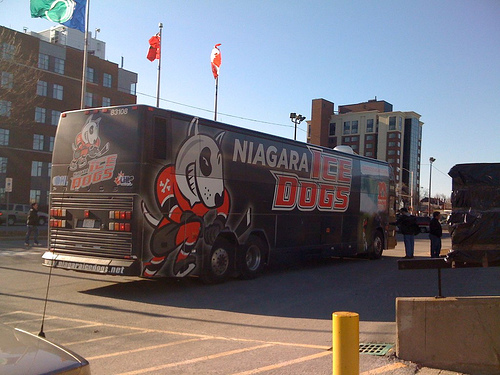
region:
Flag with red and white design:
[205, 38, 227, 78]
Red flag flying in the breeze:
[143, 29, 163, 65]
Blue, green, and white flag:
[26, 0, 91, 34]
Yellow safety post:
[323, 310, 364, 374]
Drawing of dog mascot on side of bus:
[142, 113, 227, 282]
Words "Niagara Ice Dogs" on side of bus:
[232, 140, 354, 212]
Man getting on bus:
[387, 200, 422, 260]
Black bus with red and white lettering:
[226, 130, 349, 218]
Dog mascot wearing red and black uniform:
[137, 118, 244, 282]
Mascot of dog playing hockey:
[133, 129, 237, 284]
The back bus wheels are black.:
[204, 233, 269, 279]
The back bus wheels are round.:
[207, 233, 268, 283]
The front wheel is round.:
[370, 228, 385, 256]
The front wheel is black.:
[370, 225, 382, 253]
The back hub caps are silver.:
[213, 251, 266, 273]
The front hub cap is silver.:
[373, 234, 385, 256]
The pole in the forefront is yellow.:
[325, 305, 365, 370]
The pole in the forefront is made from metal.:
[326, 313, 367, 372]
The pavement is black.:
[253, 285, 324, 319]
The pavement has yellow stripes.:
[110, 320, 290, 373]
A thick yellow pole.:
[330, 307, 362, 374]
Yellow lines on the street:
[4, 307, 412, 374]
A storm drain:
[335, 333, 395, 358]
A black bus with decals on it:
[42, 103, 399, 279]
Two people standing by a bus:
[387, 198, 447, 259]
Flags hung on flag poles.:
[27, 0, 233, 120]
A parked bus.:
[44, 98, 401, 286]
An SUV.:
[3, 198, 50, 229]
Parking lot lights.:
[290, 103, 437, 232]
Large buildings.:
[0, 15, 422, 229]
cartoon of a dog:
[153, 114, 248, 296]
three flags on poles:
[19, 3, 234, 81]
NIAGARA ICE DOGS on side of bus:
[230, 137, 367, 219]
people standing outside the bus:
[383, 194, 478, 267]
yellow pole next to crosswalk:
[310, 308, 408, 373]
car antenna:
[27, 177, 101, 374]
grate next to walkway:
[346, 333, 393, 366]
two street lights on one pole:
[279, 106, 311, 141]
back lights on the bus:
[49, 198, 156, 239]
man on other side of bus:
[5, 192, 76, 256]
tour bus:
[83, 106, 408, 258]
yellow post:
[320, 303, 360, 363]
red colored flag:
[139, 27, 171, 52]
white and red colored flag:
[197, 37, 228, 72]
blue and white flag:
[57, 1, 95, 25]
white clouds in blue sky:
[251, 9, 278, 51]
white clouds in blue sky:
[333, 39, 355, 60]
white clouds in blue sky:
[410, 49, 442, 94]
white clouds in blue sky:
[343, 10, 384, 74]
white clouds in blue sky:
[444, 21, 488, 89]